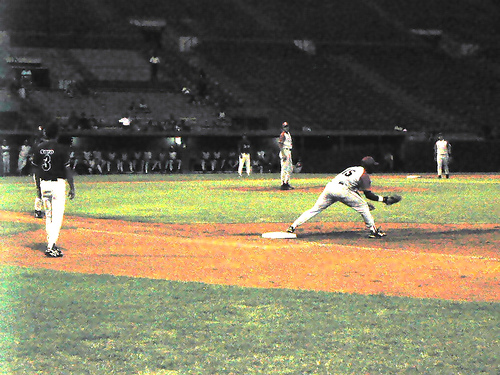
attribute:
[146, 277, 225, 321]
grassy part — green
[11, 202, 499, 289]
line — white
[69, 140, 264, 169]
players — seated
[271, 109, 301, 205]
pitcher — looking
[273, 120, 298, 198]
pitcher — tall, standing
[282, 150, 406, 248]
player — leaning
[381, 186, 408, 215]
glove — leather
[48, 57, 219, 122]
seating — rectangular, squared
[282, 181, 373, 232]
pants — white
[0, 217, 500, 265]
baseline — white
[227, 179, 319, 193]
part — pitcher's mound, dirt